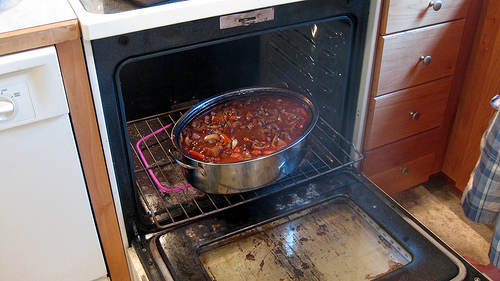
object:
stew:
[179, 93, 312, 164]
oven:
[114, 17, 481, 279]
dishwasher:
[0, 46, 113, 281]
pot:
[169, 87, 318, 194]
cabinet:
[358, 0, 470, 194]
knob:
[423, 55, 431, 67]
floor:
[387, 180, 494, 266]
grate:
[127, 82, 364, 229]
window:
[196, 198, 414, 279]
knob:
[428, 1, 442, 13]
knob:
[408, 111, 420, 120]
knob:
[398, 166, 410, 177]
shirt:
[463, 85, 498, 264]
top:
[69, 1, 311, 41]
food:
[185, 221, 327, 270]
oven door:
[127, 165, 493, 280]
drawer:
[378, 0, 468, 37]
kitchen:
[0, 0, 499, 280]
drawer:
[373, 17, 467, 96]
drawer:
[362, 73, 455, 149]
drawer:
[359, 125, 439, 189]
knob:
[0, 100, 17, 124]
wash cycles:
[1, 91, 25, 125]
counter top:
[0, 1, 79, 57]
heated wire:
[136, 120, 191, 192]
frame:
[30, 19, 130, 280]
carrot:
[220, 132, 231, 144]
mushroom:
[203, 134, 220, 141]